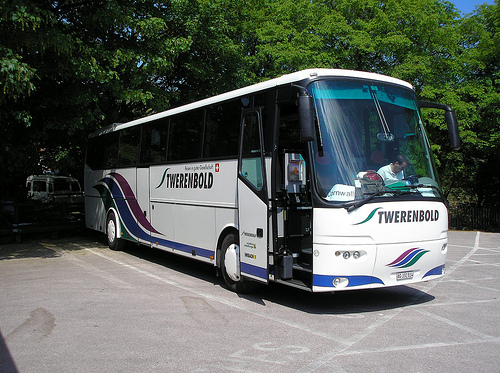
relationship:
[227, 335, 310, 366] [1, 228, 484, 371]
es on ground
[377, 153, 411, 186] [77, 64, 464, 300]
man in a bus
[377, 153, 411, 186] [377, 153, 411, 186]
man in a man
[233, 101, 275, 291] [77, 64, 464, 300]
door of a bus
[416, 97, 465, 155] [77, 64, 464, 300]
mirror on bus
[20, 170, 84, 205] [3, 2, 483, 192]
van past trees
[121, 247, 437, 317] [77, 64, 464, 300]
shadow under a bus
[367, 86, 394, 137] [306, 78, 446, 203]
wipers on windshield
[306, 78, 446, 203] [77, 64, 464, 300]
windshield of bus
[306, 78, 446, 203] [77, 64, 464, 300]
windshield on a bus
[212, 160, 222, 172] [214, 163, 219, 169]
square with cross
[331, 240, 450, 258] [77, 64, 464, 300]
headlights on front of bus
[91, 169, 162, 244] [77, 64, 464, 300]
stripes on bus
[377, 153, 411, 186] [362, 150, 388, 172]
man slumped in driver's seat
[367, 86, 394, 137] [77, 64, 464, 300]
wipers on front of bus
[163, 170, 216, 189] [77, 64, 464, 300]
twerenbold written on side of bus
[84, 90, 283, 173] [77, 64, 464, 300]
windows on side of bus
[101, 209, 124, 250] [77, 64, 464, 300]
back wheel mounted on bus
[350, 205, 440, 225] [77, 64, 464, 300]
logo painted on bus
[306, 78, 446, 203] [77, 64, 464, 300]
windshield built into bus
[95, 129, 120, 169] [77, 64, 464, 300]
side window built into bus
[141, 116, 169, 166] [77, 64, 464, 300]
side window built into bus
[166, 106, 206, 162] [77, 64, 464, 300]
side window built into bus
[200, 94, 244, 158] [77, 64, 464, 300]
side window built into bus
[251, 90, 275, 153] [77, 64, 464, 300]
side window built into bus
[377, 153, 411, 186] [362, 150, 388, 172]
man sitting in driver's seat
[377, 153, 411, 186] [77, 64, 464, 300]
man sitting in bus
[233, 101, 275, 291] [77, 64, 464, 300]
door leading to bus